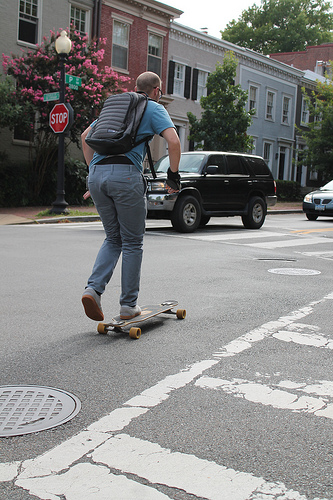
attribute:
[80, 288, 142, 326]
shoes — gray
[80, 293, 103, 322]
soles — orange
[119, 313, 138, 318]
soles — orange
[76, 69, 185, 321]
man — black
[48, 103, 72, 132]
stop sign — red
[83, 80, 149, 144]
backpack — gray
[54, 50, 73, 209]
pole — light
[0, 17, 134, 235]
tree — in city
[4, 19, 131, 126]
flowers — pink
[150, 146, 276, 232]
truck — black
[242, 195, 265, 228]
tire — black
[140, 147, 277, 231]
vehicle — large, black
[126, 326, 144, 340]
wheel — dark, yellow, skateboard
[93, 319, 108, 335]
wheel — dark, yellow, skateboard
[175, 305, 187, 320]
wheel — dark, yellow, skateboard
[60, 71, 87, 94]
sign — green, street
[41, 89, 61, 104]
sign — green, street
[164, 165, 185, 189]
glove — fingerless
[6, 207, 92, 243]
corner — street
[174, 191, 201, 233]
tire — black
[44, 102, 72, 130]
sign — stop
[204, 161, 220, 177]
mirror — side